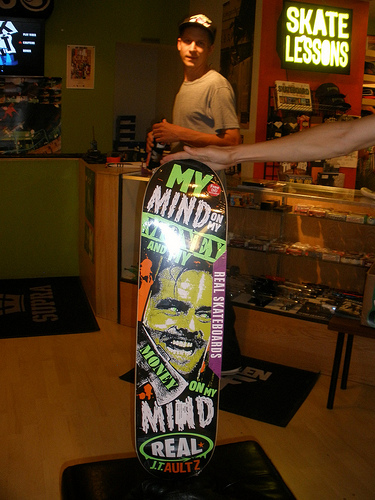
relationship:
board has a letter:
[156, 172, 222, 398] [137, 398, 169, 434]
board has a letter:
[156, 172, 222, 398] [176, 195, 195, 223]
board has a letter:
[156, 172, 222, 398] [148, 186, 171, 215]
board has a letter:
[156, 172, 222, 398] [193, 396, 214, 425]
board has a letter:
[156, 172, 222, 398] [174, 400, 200, 430]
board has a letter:
[156, 172, 222, 398] [173, 434, 189, 458]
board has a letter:
[156, 172, 222, 398] [163, 436, 177, 459]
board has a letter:
[156, 172, 222, 398] [139, 400, 164, 434]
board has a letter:
[156, 172, 222, 398] [163, 402, 175, 430]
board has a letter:
[156, 172, 222, 398] [198, 396, 208, 425]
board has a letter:
[156, 172, 222, 398] [150, 436, 167, 457]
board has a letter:
[156, 172, 222, 398] [174, 196, 191, 222]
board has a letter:
[156, 172, 222, 398] [177, 438, 189, 458]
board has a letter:
[156, 172, 222, 398] [189, 437, 203, 454]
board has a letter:
[156, 172, 222, 398] [193, 199, 208, 228]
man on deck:
[141, 7, 244, 387] [15, 336, 342, 486]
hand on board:
[158, 147, 228, 172] [129, 153, 206, 481]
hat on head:
[173, 13, 220, 45] [174, 13, 218, 72]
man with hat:
[141, 7, 244, 387] [173, 13, 220, 45]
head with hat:
[174, 13, 218, 72] [173, 13, 220, 45]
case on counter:
[237, 193, 360, 323] [241, 180, 363, 325]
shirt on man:
[179, 84, 233, 149] [148, 14, 249, 369]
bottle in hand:
[147, 130, 166, 171] [143, 123, 170, 160]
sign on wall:
[287, 2, 348, 74] [258, 8, 355, 121]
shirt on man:
[171, 68, 240, 148] [172, 8, 236, 376]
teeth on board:
[166, 343, 193, 355] [156, 172, 222, 398]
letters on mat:
[25, 280, 69, 329] [2, 276, 95, 341]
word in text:
[139, 395, 213, 433] [143, 408, 209, 422]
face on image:
[144, 262, 214, 377] [145, 253, 208, 381]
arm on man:
[157, 113, 372, 175] [170, 115, 363, 211]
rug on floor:
[225, 352, 293, 424] [48, 346, 341, 450]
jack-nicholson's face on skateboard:
[142, 253, 212, 379] [132, 155, 224, 484]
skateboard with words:
[132, 155, 224, 484] [142, 162, 228, 433]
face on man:
[177, 37, 206, 69] [141, 7, 244, 387]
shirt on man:
[171, 68, 240, 148] [141, 7, 244, 387]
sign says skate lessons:
[287, 2, 348, 74] [286, 4, 351, 66]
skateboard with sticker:
[132, 155, 224, 484] [201, 180, 219, 200]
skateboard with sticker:
[132, 155, 224, 484] [136, 427, 211, 468]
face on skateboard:
[144, 262, 214, 377] [132, 155, 224, 484]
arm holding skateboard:
[157, 113, 372, 175] [132, 155, 224, 484]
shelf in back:
[114, 112, 135, 131] [4, 24, 165, 280]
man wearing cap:
[141, 7, 244, 387] [173, 10, 220, 44]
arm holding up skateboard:
[157, 113, 372, 175] [132, 155, 224, 484]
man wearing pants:
[141, 7, 244, 387] [221, 289, 244, 372]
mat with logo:
[0, 272, 103, 340] [1, 280, 64, 329]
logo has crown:
[1, 280, 64, 329] [2, 287, 29, 318]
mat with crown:
[0, 272, 103, 340] [2, 287, 29, 318]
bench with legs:
[315, 311, 372, 413] [320, 330, 358, 411]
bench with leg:
[315, 311, 372, 413] [335, 334, 355, 391]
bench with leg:
[315, 311, 372, 413] [321, 330, 346, 410]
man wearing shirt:
[141, 7, 244, 387] [171, 68, 240, 148]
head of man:
[174, 13, 218, 72] [141, 7, 244, 387]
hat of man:
[173, 13, 220, 45] [141, 7, 244, 387]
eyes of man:
[179, 34, 209, 50] [141, 7, 244, 387]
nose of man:
[185, 37, 201, 56] [141, 7, 244, 387]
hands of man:
[141, 114, 170, 156] [141, 7, 244, 387]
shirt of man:
[171, 68, 240, 148] [141, 7, 244, 387]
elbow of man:
[216, 131, 239, 147] [144, 13, 239, 352]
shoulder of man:
[199, 69, 233, 104] [144, 13, 239, 352]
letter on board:
[150, 440, 166, 456] [131, 162, 227, 477]